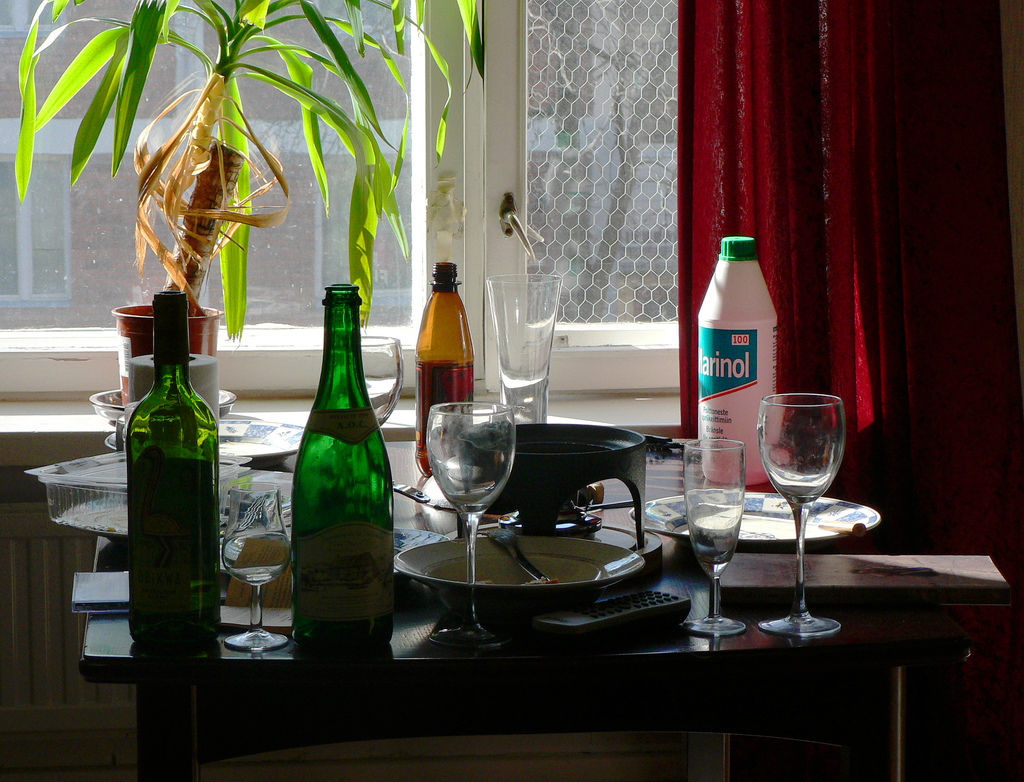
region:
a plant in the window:
[21, 5, 492, 296]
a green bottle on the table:
[302, 279, 388, 660]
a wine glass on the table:
[434, 392, 512, 649]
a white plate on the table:
[386, 535, 642, 596]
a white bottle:
[699, 241, 769, 472]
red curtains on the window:
[672, 13, 1014, 498]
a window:
[1, 1, 692, 425]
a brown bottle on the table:
[412, 266, 474, 470]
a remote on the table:
[541, 576, 681, 625]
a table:
[27, 463, 1012, 716]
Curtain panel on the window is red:
[684, 5, 1020, 565]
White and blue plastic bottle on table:
[700, 236, 786, 486]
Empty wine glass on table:
[756, 377, 849, 643]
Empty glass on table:
[683, 437, 748, 640]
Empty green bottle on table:
[294, 270, 397, 653]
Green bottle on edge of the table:
[134, 289, 226, 647]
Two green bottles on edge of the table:
[118, 271, 404, 652]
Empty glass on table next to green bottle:
[422, 396, 509, 656]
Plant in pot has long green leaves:
[13, 2, 488, 394]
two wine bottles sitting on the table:
[122, 278, 407, 630]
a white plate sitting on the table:
[404, 524, 640, 598]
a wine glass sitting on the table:
[759, 389, 849, 645]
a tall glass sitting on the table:
[487, 271, 571, 423]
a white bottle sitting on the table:
[689, 234, 785, 479]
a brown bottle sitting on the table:
[416, 263, 473, 472]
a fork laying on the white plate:
[474, 515, 552, 586]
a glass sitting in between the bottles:
[221, 483, 301, 651]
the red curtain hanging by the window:
[676, 4, 1022, 779]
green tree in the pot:
[19, 6, 468, 326]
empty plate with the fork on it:
[403, 499, 669, 627]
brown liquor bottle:
[406, 236, 501, 493]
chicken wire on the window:
[517, 3, 677, 335]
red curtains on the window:
[672, 2, 1020, 748]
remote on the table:
[536, 559, 701, 643]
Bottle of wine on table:
[88, 239, 262, 638]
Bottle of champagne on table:
[262, 272, 441, 640]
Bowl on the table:
[392, 521, 633, 630]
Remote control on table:
[505, 572, 715, 650]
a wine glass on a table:
[759, 394, 839, 636]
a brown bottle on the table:
[419, 263, 473, 457]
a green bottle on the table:
[302, 287, 401, 643]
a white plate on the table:
[395, 537, 634, 589]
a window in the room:
[6, 113, 696, 366]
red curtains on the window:
[676, 116, 1015, 486]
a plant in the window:
[19, 110, 408, 311]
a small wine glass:
[227, 477, 294, 632]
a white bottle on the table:
[698, 239, 776, 481]